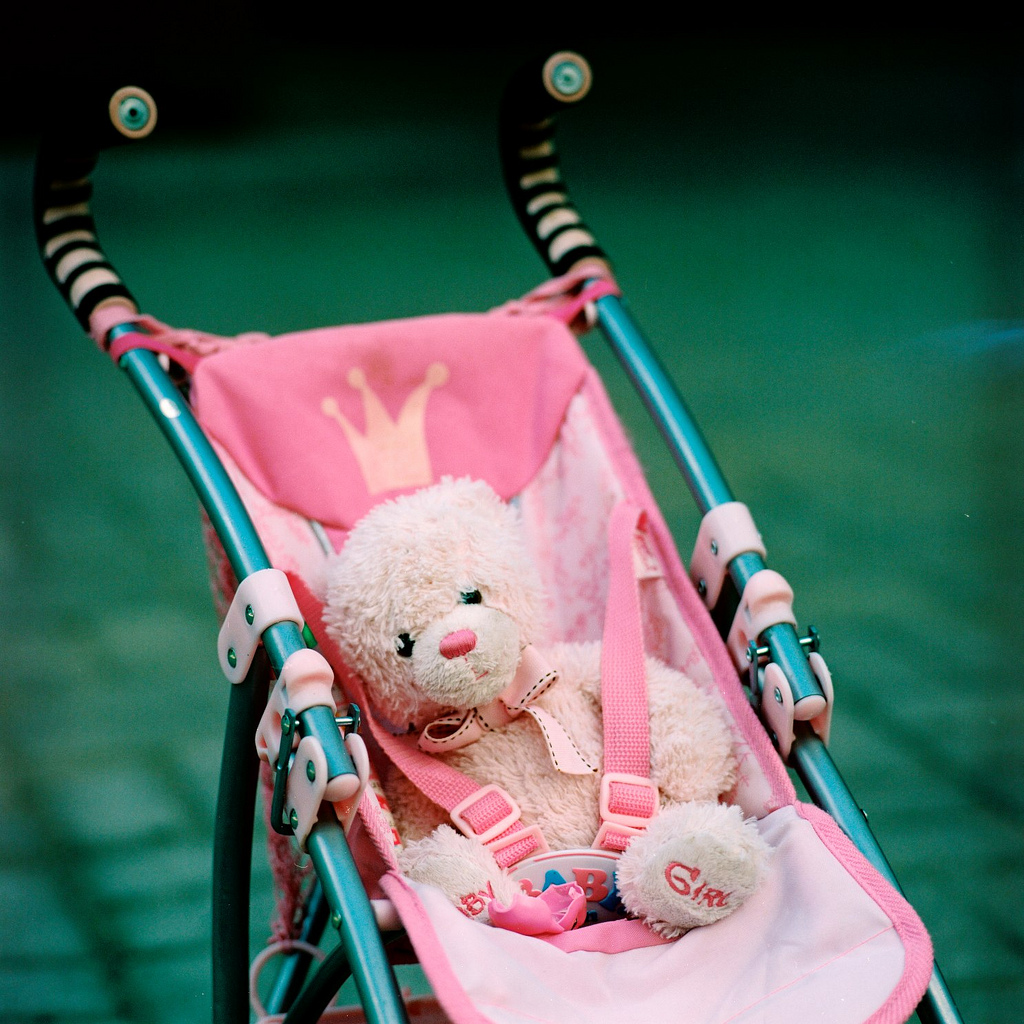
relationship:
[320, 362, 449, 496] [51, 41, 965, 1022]
crown inside stroller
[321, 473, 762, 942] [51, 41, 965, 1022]
"baby girl" strapped into stroller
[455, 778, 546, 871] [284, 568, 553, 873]
buckle on strap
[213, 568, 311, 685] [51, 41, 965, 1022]
clamp on stroller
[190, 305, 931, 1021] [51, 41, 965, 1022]
cloth on stroller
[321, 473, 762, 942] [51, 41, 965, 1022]
"baby girl" in stroller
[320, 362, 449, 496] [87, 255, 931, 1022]
crown on cloth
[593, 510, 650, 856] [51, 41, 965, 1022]
straps for stroller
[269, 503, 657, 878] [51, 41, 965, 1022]
straps for stroller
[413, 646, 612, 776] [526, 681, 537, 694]
bow with dots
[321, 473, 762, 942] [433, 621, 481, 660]
"baby girl" with nose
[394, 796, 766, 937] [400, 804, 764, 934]
"baby girl" written on feet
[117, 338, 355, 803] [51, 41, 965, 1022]
bars on stroller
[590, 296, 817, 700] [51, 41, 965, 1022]
bars on stroller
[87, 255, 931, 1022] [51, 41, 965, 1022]
cloth on stroller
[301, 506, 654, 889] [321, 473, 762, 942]
straps holding "baby girl"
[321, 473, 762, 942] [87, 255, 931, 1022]
"baby girl" in cloth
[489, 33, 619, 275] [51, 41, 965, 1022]
handle on stroller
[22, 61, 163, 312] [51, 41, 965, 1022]
handle on stroller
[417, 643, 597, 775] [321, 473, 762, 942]
bow on "baby girl"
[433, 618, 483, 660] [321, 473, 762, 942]
nose on "baby girl"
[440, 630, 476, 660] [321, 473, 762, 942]
nose on the "baby girl"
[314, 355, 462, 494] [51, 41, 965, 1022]
crown on the back of the stroller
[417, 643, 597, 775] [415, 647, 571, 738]
bow around the neck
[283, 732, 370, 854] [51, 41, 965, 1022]
screws of  the stroller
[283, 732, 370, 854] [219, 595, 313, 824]
screws with screws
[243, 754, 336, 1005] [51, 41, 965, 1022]
chain hanging from the stroller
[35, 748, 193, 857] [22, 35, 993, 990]
squares on the ground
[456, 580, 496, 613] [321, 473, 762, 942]
button as the eye on the "baby girl"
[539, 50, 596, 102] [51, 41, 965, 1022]
circle at the top of the stroller